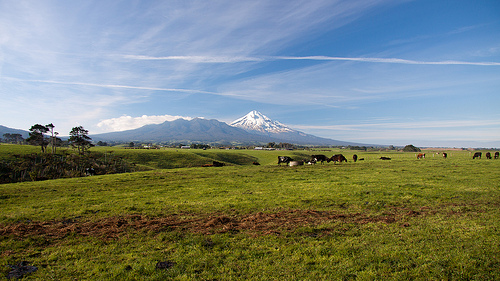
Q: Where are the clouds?
A: The sky.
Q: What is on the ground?
A: Grass and dirt.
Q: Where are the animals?
A: On the field.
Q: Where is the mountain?
A: In background.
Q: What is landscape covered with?
A: Grass.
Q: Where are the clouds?
A: In sky.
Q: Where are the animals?
A: In background.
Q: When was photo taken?
A: During daytime.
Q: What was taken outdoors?
A: Photo.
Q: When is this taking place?
A: Daytime.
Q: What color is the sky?
A: Blue and white.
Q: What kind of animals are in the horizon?
A: Cows.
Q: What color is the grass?
A: Green.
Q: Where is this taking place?
A: In a field.